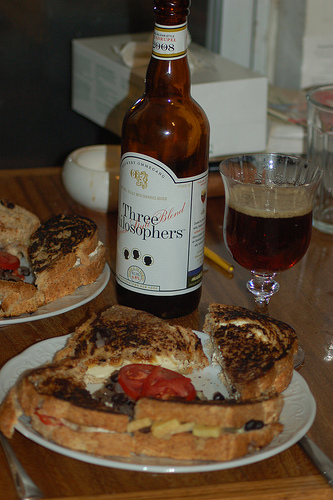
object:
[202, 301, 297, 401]
bread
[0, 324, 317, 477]
plate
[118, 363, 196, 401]
tomato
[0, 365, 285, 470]
sandwich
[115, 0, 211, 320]
bottle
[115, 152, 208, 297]
label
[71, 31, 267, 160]
box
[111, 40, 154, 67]
tissues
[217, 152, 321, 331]
glass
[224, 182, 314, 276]
beer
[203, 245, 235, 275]
pencil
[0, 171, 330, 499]
table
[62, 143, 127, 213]
dish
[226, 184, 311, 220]
foam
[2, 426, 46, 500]
silverware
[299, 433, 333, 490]
handle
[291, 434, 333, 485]
utensil